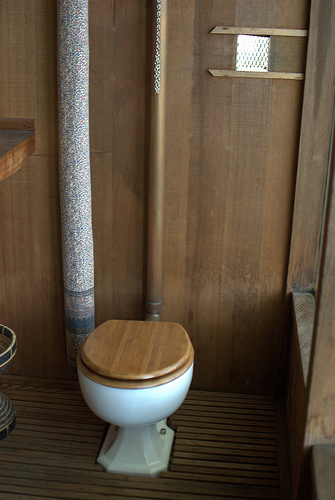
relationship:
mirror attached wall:
[214, 22, 291, 110] [88, 6, 287, 331]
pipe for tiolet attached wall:
[54, 7, 99, 339] [155, 137, 259, 230]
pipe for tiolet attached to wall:
[54, 7, 99, 339] [4, 4, 304, 404]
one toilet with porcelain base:
[75, 306, 195, 477] [95, 421, 180, 474]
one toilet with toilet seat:
[75, 306, 195, 477] [75, 313, 204, 397]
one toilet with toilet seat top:
[75, 306, 195, 477] [77, 305, 191, 381]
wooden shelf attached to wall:
[0, 110, 43, 191] [4, 4, 304, 404]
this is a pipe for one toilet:
[143, 0, 175, 316] [75, 306, 195, 477]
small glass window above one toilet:
[234, 31, 270, 73] [75, 306, 195, 477]